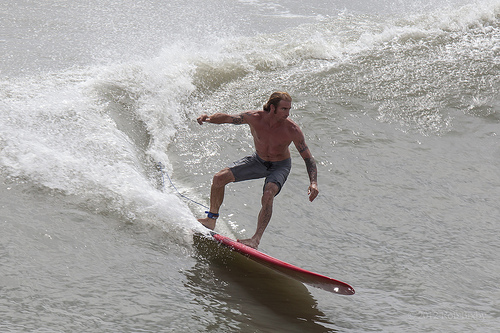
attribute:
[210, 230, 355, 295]
board — red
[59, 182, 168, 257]
ocean waves — white, green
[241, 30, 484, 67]
waves — green, white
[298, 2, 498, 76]
wave — white, green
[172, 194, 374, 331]
board — red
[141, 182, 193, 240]
ocean waves — green, white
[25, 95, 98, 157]
ocean waves — green, white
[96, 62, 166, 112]
ocean waves — green, white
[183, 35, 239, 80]
ocean waves — green, white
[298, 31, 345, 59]
ocean waves — green, white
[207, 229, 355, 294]
surfboard — wooden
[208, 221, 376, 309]
surfboard — red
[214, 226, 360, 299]
surfboard — red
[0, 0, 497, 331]
waves — white, green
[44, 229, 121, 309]
ripples — big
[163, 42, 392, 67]
waves — white, green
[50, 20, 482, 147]
waves — white, green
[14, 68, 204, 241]
waves — white, green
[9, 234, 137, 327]
waves — green, white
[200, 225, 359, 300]
board — red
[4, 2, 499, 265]
waves — white, green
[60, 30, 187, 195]
waves — white, green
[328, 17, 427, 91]
ocean waves — white and green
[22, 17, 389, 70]
water — splashing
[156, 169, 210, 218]
cord — blue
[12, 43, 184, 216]
waves — white, green